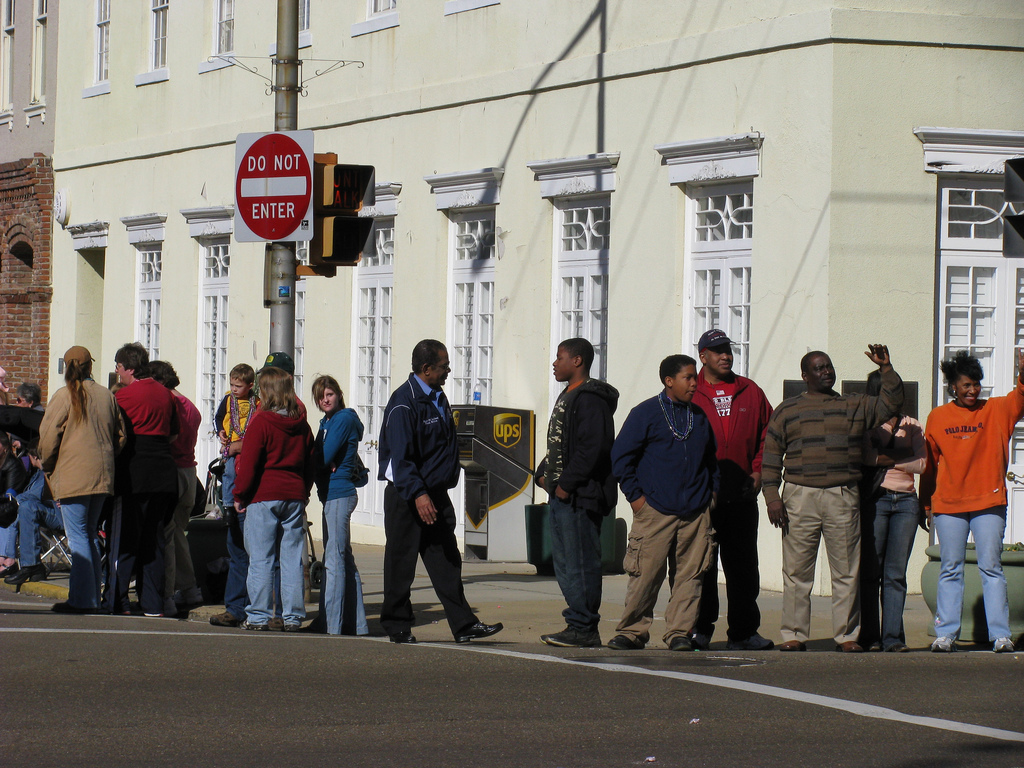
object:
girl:
[299, 375, 370, 635]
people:
[0, 328, 1024, 652]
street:
[3, 575, 1022, 761]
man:
[761, 344, 904, 654]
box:
[449, 405, 536, 562]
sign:
[235, 130, 314, 242]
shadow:
[469, 0, 608, 384]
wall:
[2, 2, 1021, 551]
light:
[309, 152, 375, 265]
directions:
[334, 169, 361, 209]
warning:
[249, 155, 301, 220]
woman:
[232, 367, 315, 630]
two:
[761, 344, 1024, 652]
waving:
[865, 344, 1024, 430]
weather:
[5, 2, 1018, 768]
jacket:
[692, 367, 774, 497]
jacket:
[36, 380, 126, 502]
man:
[378, 339, 504, 643]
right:
[610, 0, 1023, 684]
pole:
[269, 0, 294, 363]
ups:
[495, 424, 519, 443]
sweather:
[761, 364, 904, 505]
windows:
[692, 180, 753, 386]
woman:
[38, 346, 129, 614]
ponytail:
[65, 362, 89, 426]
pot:
[922, 544, 1023, 643]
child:
[214, 363, 260, 528]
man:
[255, 352, 294, 376]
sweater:
[920, 378, 1024, 515]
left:
[0, 165, 361, 762]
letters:
[945, 422, 984, 434]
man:
[608, 354, 721, 651]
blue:
[611, 389, 721, 515]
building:
[0, 156, 54, 408]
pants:
[780, 481, 862, 646]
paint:
[2, 575, 70, 600]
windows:
[120, 125, 1024, 546]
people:
[761, 344, 1024, 654]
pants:
[380, 482, 479, 642]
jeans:
[60, 493, 107, 609]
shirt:
[703, 377, 738, 442]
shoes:
[931, 637, 1014, 654]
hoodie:
[232, 406, 315, 506]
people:
[213, 352, 371, 636]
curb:
[5, 562, 1020, 652]